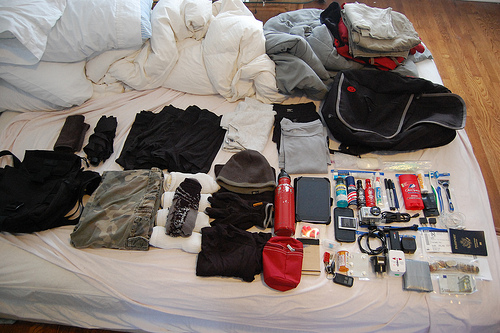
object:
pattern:
[64, 194, 91, 219]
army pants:
[71, 168, 165, 251]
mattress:
[0, 49, 500, 333]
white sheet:
[80, 0, 286, 104]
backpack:
[321, 69, 467, 154]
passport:
[449, 228, 488, 256]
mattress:
[4, 45, 490, 325]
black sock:
[53, 114, 90, 151]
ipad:
[293, 177, 333, 225]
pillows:
[0, 0, 151, 66]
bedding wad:
[0, 0, 288, 112]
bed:
[1, 3, 498, 330]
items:
[333, 167, 455, 244]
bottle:
[275, 168, 295, 235]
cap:
[216, 149, 276, 193]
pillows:
[0, 0, 153, 114]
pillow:
[0, 0, 67, 65]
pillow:
[39, 0, 151, 63]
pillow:
[0, 61, 93, 111]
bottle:
[336, 177, 348, 207]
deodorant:
[399, 174, 425, 209]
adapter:
[356, 228, 417, 277]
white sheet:
[0, 56, 500, 333]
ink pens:
[383, 178, 399, 209]